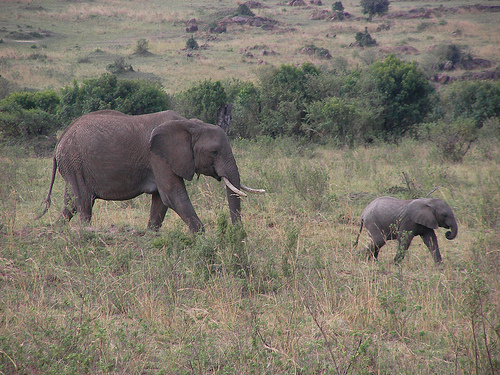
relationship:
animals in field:
[25, 86, 461, 270] [0, 136, 493, 374]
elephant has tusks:
[38, 108, 273, 237] [217, 173, 265, 199]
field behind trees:
[1, 5, 494, 87] [7, 59, 492, 139]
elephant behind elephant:
[38, 108, 273, 237] [348, 192, 463, 271]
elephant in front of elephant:
[348, 192, 463, 271] [38, 108, 273, 237]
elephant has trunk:
[348, 192, 463, 271] [443, 216, 460, 242]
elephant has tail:
[38, 108, 273, 237] [38, 152, 65, 217]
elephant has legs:
[38, 108, 273, 237] [58, 184, 211, 237]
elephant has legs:
[348, 192, 463, 271] [365, 232, 447, 269]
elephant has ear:
[38, 108, 273, 237] [146, 125, 199, 179]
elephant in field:
[348, 192, 463, 271] [0, 136, 493, 374]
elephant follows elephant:
[38, 108, 273, 237] [348, 192, 463, 271]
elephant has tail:
[348, 192, 463, 271] [349, 212, 371, 251]